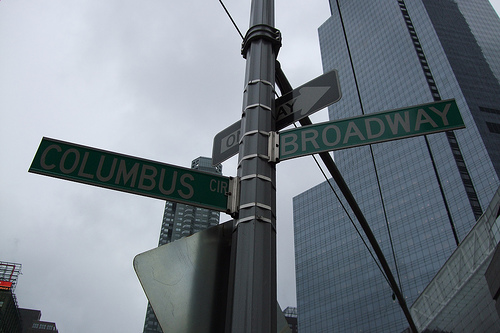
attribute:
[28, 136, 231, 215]
street sign — green, white, columbus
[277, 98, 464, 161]
street sign — green, broadway, white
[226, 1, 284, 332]
pole — metal, gray, black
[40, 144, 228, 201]
writing — white, bold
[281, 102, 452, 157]
writing — white, bold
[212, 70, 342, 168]
sign — black, white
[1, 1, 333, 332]
sky — gray, cloudy, blue, white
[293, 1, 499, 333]
building — tall, glass, large, many floors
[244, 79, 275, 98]
ring — metal, silver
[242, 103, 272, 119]
ring — metal, silver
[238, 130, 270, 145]
ring — metal, silver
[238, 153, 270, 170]
ring — metal, silver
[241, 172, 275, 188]
ring — metal, silver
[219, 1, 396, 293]
wire — black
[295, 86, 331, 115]
arrow — white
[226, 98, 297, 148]
writing — black, bold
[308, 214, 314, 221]
window — glass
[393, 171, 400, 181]
window — glass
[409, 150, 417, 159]
window — glass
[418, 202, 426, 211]
window — glass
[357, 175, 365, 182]
window — glass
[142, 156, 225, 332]
building — tall, large, many floors